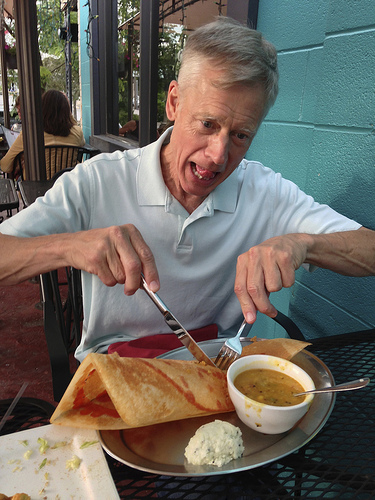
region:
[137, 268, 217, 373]
Man is holding a knife.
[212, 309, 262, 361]
Man is holding a fork.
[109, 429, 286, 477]
The plate is silver.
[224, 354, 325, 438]
Small cup of soup.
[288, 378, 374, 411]
Piece of silverware in the cup.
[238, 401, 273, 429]
Soup on the outside of the cup.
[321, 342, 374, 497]
The table is black.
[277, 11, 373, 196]
The wall is greenish blue.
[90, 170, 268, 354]
The shirt is light blue.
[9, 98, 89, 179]
Woman sitting in a chair.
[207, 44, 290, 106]
Man has gray hair.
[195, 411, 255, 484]
Scoop of white potatoes on plate.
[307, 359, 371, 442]
Silver utensil in bowl.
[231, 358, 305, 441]
White bowl of soup on plate.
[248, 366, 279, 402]
Soup inside of soup cup.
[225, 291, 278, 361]
Person has fork in left hand.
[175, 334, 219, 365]
Person has knife in right hand.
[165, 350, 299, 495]
Food on top of plate.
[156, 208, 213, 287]
Man wearing white shirt.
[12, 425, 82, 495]
White plate on table.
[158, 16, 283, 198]
the head of a man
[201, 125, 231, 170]
the nose of a man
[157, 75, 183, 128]
the ear of a man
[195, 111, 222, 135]
the eye of a man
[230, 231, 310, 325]
the hand of a man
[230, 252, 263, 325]
the finger of a man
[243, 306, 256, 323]
the finger nail of a man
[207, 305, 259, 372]
a gray metal fork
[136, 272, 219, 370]
a gray metal knife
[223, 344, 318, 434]
a small white bowl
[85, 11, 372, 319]
a man with gray hair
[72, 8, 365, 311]
an older man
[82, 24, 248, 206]
a man making a face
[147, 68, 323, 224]
a man with his tounge out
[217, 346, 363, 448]
a bowl of soup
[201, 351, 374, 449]
a spoon in the bowl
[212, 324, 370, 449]
a white bowl of soup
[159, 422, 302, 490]
a lump of potato salad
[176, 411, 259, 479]
potato salad on a platter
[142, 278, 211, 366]
silver butter knife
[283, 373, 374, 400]
hand of a soup spoon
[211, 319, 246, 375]
bottom of a fork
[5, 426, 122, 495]
corner of a white plate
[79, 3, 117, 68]
hanging christmas lights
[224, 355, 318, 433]
bowl of orange soup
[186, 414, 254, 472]
pile of white creamy food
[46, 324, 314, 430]
large tortilla like food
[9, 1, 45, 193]
small brown edged pillar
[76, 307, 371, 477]
silver oval shaped plate